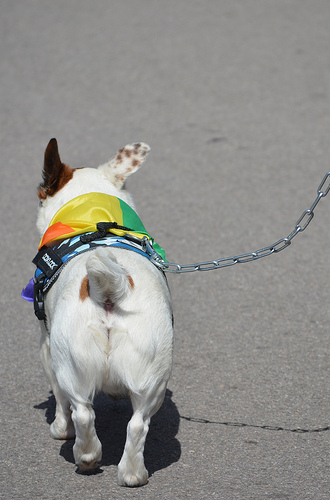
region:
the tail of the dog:
[77, 247, 134, 313]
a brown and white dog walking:
[18, 136, 202, 472]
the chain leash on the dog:
[132, 156, 325, 281]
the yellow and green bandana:
[30, 189, 173, 256]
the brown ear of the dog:
[32, 131, 79, 202]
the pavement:
[186, 283, 318, 496]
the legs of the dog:
[26, 356, 181, 497]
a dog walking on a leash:
[8, 115, 205, 477]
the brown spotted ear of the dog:
[93, 137, 160, 188]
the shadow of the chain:
[173, 390, 327, 448]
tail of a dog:
[78, 246, 138, 304]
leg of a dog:
[60, 344, 109, 474]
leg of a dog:
[106, 346, 176, 491]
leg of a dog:
[38, 333, 78, 445]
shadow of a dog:
[28, 368, 193, 477]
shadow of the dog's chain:
[162, 390, 329, 440]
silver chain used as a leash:
[104, 165, 328, 272]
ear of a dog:
[33, 137, 70, 191]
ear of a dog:
[100, 137, 155, 181]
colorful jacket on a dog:
[18, 187, 176, 321]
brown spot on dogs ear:
[124, 149, 132, 158]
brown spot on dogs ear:
[117, 146, 125, 152]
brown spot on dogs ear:
[116, 153, 123, 161]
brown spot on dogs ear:
[133, 141, 142, 148]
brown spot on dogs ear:
[130, 147, 141, 154]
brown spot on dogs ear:
[141, 144, 149, 148]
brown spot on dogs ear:
[140, 149, 148, 157]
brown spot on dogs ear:
[130, 156, 140, 167]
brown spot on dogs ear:
[119, 175, 125, 182]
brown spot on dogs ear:
[113, 172, 120, 180]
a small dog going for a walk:
[20, 142, 318, 487]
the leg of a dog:
[120, 387, 157, 493]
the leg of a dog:
[65, 385, 109, 472]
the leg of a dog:
[38, 361, 70, 443]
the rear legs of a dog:
[70, 410, 160, 491]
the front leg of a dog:
[46, 378, 70, 442]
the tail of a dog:
[84, 248, 135, 297]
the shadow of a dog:
[43, 393, 184, 476]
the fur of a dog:
[53, 302, 92, 377]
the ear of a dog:
[35, 137, 64, 193]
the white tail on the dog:
[85, 243, 127, 303]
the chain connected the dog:
[123, 170, 328, 273]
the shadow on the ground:
[32, 388, 328, 479]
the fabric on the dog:
[20, 192, 168, 300]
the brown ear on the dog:
[41, 136, 60, 184]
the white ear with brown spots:
[101, 143, 150, 190]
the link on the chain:
[176, 264, 198, 272]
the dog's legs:
[37, 334, 165, 486]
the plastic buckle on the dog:
[32, 287, 44, 320]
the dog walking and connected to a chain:
[19, 137, 329, 486]